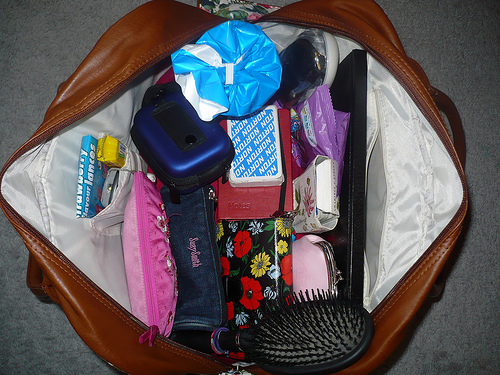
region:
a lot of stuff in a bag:
[28, 16, 455, 318]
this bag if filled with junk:
[60, 47, 427, 364]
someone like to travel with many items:
[74, 59, 329, 335]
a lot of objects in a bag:
[69, 66, 356, 317]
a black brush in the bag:
[237, 298, 381, 368]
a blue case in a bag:
[123, 98, 239, 197]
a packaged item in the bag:
[210, 100, 289, 190]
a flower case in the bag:
[219, 209, 295, 317]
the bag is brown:
[47, 9, 184, 129]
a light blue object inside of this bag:
[179, 24, 295, 134]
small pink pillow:
[122, 170, 182, 346]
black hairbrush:
[175, 293, 373, 371]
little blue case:
[129, 90, 234, 188]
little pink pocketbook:
[290, 232, 339, 304]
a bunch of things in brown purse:
[75, 22, 372, 363]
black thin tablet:
[331, 50, 365, 310]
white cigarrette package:
[288, 158, 339, 233]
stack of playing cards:
[225, 101, 283, 184]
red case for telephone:
[214, 103, 290, 228]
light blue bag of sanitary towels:
[175, 15, 284, 119]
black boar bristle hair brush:
[172, 285, 374, 372]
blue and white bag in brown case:
[168, 26, 289, 123]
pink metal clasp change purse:
[288, 229, 347, 300]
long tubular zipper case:
[159, 183, 228, 350]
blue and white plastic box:
[225, 105, 286, 190]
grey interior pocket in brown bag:
[76, 133, 138, 227]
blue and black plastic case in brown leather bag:
[122, 89, 235, 199]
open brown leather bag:
[3, 0, 478, 374]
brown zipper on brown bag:
[266, 16, 470, 315]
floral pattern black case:
[212, 212, 299, 357]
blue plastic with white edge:
[166, 13, 285, 120]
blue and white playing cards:
[225, 100, 285, 187]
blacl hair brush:
[223, 282, 374, 368]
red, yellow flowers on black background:
[218, 218, 295, 325]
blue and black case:
[128, 91, 238, 196]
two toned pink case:
[116, 176, 180, 341]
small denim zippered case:
[161, 181, 225, 337]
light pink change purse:
[285, 231, 350, 307]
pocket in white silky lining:
[359, 67, 462, 309]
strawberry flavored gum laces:
[68, 130, 96, 223]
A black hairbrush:
[187, 290, 362, 369]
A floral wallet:
[223, 218, 296, 319]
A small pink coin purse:
[297, 236, 339, 292]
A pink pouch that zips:
[121, 164, 172, 334]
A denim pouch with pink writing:
[165, 193, 222, 333]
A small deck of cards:
[230, 115, 280, 181]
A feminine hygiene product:
[295, 96, 341, 154]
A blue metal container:
[135, 87, 231, 187]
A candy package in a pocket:
[96, 126, 126, 166]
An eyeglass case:
[280, 26, 337, 98]